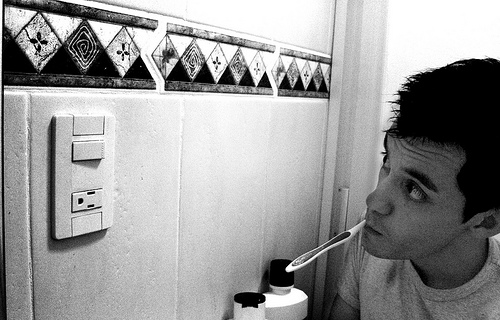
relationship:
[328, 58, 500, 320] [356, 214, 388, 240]
boy in mouth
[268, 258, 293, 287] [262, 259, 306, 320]
black lid on bottle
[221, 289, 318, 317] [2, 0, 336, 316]
bottle near wall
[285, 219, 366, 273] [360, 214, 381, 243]
fire hydrant in mouth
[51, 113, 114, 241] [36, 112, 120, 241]
light on wall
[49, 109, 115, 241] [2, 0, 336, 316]
light on wall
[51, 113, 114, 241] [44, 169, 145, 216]
light on outlet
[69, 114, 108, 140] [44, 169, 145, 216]
switch on outlet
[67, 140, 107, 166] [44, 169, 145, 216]
switch on outlet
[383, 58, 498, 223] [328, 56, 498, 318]
hair on boy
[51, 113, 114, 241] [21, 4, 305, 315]
light on wall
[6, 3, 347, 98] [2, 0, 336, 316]
border on wall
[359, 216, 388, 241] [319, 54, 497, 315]
mouth on man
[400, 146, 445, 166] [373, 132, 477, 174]
wrinkles on forehead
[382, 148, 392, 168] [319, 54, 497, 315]
eye on man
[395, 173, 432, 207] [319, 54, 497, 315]
eye on man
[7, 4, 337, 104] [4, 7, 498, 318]
tiles in bathroom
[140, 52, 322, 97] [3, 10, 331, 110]
patterns on tile